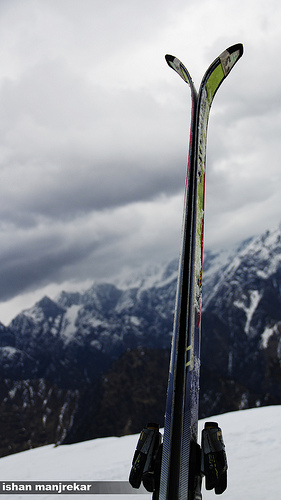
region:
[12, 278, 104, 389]
scenic mountain view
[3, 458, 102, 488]
light fluffy snow covering ground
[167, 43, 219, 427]
green red and blue downhill skis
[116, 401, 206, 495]
mounted ski boot brackets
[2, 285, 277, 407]
cold snowy mountain scene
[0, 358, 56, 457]
isolated snowy mountain downhill ski hill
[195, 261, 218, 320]
yellow decal on downhill skis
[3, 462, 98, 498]
news journalist listed on screen shot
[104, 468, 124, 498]
television reporter on ski hill scene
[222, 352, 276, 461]
tree covered mountains behind snow hill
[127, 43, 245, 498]
Skis standing in snow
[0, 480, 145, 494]
Watermark on shot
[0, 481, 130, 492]
Watermark says ishan manjrekar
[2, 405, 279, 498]
The snow is white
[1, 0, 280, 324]
Sky is dark and cloudy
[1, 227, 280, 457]
Large moutains and rocks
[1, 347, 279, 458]
Brown rocks are in front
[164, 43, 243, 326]
Skis have yellow and red stripes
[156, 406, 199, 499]
Cross marks on skis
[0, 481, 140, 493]
Watermark is gray with white letters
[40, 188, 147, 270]
the sky is very dark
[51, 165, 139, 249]
the sky is very dark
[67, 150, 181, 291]
the sky is very dark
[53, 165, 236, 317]
the sky is very dark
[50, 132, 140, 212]
the sky is very dark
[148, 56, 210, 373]
a pair of snow skies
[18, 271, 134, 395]
A mountain top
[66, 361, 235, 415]
A big rock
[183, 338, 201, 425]
Ice and snow on the skies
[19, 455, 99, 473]
Snow on the hill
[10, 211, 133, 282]
Dark snow clouds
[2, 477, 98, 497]
Possible a name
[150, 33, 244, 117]
ront tips of the skies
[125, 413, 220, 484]
Straps for holding the feet in place.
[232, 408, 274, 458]
Up the hill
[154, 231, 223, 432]
a pair of skis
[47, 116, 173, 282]
Gray, white clouds in the background.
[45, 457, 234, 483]
A mound of snow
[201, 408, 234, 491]
ski bindings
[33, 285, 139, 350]
snow-covered mountains.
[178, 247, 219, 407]
the ski is blue,green and red.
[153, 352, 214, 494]
these skis are bond together.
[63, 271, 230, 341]
the mountains are dark with bits of snow on them.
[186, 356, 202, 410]
Some melting snow on the ski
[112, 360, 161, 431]
some vegetation.